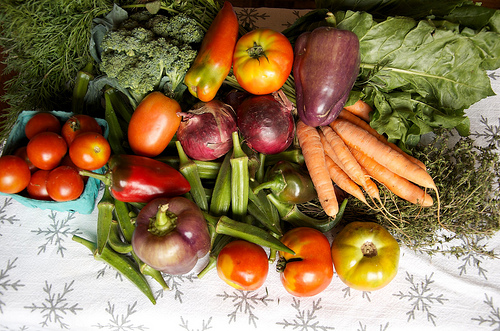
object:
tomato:
[233, 29, 293, 96]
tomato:
[131, 91, 180, 155]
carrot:
[296, 118, 338, 218]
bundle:
[297, 95, 438, 215]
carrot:
[322, 125, 367, 183]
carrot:
[330, 120, 434, 188]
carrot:
[351, 149, 435, 208]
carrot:
[342, 97, 375, 120]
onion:
[178, 102, 237, 159]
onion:
[238, 94, 296, 157]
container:
[0, 108, 111, 215]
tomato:
[50, 165, 84, 203]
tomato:
[71, 133, 113, 166]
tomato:
[25, 110, 63, 139]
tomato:
[0, 154, 31, 195]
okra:
[230, 129, 249, 217]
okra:
[172, 141, 209, 208]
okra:
[201, 213, 296, 255]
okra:
[70, 235, 156, 305]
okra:
[93, 177, 117, 254]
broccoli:
[99, 11, 206, 99]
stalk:
[160, 65, 185, 96]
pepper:
[183, 5, 238, 104]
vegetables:
[329, 218, 398, 289]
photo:
[0, 0, 500, 330]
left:
[1, 3, 100, 314]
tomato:
[277, 226, 334, 297]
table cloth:
[0, 155, 500, 330]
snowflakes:
[20, 279, 82, 321]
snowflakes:
[93, 294, 145, 330]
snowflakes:
[355, 316, 391, 330]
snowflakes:
[274, 296, 339, 330]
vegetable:
[336, 13, 497, 147]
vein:
[361, 62, 489, 91]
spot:
[185, 57, 223, 92]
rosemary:
[0, 1, 114, 145]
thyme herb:
[351, 136, 498, 250]